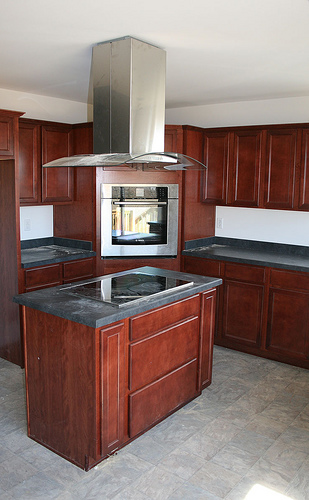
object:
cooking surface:
[13, 260, 225, 321]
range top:
[71, 270, 191, 305]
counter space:
[185, 238, 309, 269]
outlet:
[215, 216, 225, 228]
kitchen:
[0, 1, 309, 500]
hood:
[41, 35, 206, 174]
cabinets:
[201, 130, 230, 205]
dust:
[26, 289, 110, 319]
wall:
[18, 119, 79, 251]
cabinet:
[260, 127, 302, 211]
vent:
[45, 36, 209, 169]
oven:
[101, 180, 180, 255]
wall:
[199, 126, 308, 248]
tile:
[158, 445, 207, 478]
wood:
[22, 309, 100, 470]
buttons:
[112, 185, 135, 198]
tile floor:
[0, 337, 309, 499]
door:
[100, 326, 127, 456]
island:
[11, 264, 221, 473]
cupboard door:
[196, 291, 214, 394]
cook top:
[57, 271, 195, 310]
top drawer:
[128, 298, 199, 346]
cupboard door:
[229, 130, 261, 205]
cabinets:
[232, 135, 260, 207]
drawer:
[221, 265, 265, 282]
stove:
[93, 269, 173, 306]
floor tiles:
[184, 463, 240, 500]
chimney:
[41, 34, 208, 179]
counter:
[185, 239, 308, 269]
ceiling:
[0, 0, 309, 131]